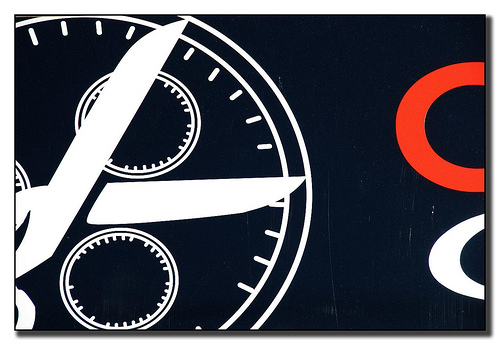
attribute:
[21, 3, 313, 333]
shape — white, oval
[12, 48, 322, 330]
gauge — white, small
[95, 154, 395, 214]
edge — curved, a point, straight , slanted 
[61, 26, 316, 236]
blades — time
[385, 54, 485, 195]
red curve — thick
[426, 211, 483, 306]
white curve — thick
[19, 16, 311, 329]
lines — parallel, white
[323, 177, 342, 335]
line — faint, white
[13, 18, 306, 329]
scissors — open, white, stencil scissors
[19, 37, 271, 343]
lines — short, inner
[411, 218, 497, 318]
line — thick, white, curved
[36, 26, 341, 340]
gauge — white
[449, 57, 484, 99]
c shape — large , red 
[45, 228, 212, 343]
circle — white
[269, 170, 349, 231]
tip — sharp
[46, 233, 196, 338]
tick marks — white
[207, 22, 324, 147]
circle — white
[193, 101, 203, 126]
lines — parallel, white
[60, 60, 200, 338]
circles — white